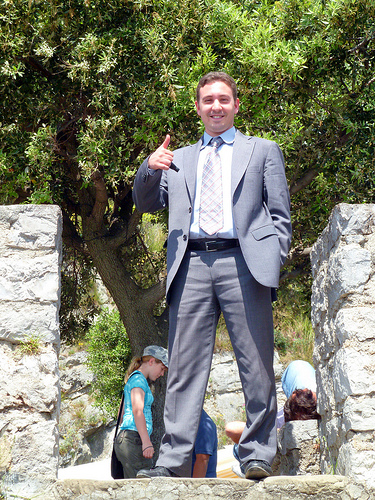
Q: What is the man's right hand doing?
A: Giving a thumbs up.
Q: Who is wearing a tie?
A: The man on the rocks.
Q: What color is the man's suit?
A: Grey.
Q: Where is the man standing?
A: Between two rocks.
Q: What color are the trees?
A: Green.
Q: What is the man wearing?
A: Suit.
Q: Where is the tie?
A: Around the man's neck.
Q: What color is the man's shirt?
A: White.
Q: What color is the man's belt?
A: Black.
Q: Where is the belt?
A: Around the man's waist.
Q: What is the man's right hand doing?
A: Giving a thumbs up.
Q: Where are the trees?
A: Behind the man.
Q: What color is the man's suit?
A: Gray.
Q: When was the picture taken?
A: Daytime.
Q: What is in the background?
A: A tree.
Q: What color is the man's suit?
A: Gray.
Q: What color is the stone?
A: White.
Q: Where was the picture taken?
A: At a park.